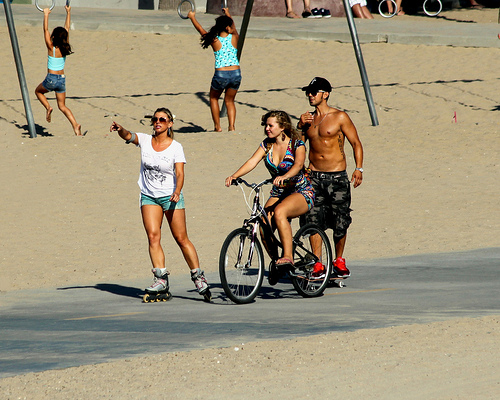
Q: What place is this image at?
A: It is at the walkway.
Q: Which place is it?
A: It is a walkway.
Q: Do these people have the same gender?
A: No, they are both male and female.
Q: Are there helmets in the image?
A: No, there are no helmets.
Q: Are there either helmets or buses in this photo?
A: No, there are no helmets or buses.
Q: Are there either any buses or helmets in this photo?
A: No, there are no helmets or buses.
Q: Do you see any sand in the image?
A: Yes, there is sand.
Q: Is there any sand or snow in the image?
A: Yes, there is sand.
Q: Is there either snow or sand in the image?
A: Yes, there is sand.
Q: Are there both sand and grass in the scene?
A: No, there is sand but no grass.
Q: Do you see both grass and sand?
A: No, there is sand but no grass.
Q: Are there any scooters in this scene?
A: No, there are no scooters.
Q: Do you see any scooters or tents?
A: No, there are no scooters or tents.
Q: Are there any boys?
A: No, there are no boys.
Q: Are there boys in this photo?
A: No, there are no boys.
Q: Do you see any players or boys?
A: No, there are no boys or players.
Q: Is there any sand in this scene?
A: Yes, there is sand.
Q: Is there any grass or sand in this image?
A: Yes, there is sand.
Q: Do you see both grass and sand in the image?
A: No, there is sand but no grass.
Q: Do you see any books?
A: No, there are no books.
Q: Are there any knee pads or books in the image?
A: No, there are no books or knee pads.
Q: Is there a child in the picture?
A: No, there are no children.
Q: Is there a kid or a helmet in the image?
A: No, there are no children or helmets.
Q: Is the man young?
A: Yes, the man is young.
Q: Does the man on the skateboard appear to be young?
A: Yes, the man is young.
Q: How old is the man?
A: The man is young.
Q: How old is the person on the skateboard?
A: The man is young.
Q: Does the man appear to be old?
A: No, the man is young.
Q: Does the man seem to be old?
A: No, the man is young.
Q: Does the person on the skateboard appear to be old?
A: No, the man is young.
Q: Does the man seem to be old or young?
A: The man is young.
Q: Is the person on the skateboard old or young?
A: The man is young.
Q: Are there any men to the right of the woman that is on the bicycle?
A: Yes, there is a man to the right of the woman.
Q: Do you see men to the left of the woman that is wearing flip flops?
A: No, the man is to the right of the woman.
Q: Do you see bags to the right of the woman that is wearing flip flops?
A: No, there is a man to the right of the woman.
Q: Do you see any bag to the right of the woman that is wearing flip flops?
A: No, there is a man to the right of the woman.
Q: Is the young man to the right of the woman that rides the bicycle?
A: Yes, the man is to the right of the woman.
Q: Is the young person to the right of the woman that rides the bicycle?
A: Yes, the man is to the right of the woman.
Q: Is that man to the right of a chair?
A: No, the man is to the right of the woman.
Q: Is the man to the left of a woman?
A: No, the man is to the right of a woman.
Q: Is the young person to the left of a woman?
A: No, the man is to the right of a woman.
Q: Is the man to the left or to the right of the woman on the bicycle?
A: The man is to the right of the woman.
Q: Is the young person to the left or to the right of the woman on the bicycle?
A: The man is to the right of the woman.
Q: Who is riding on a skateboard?
A: The man is riding on a skateboard.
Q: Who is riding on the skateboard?
A: The man is riding on a skateboard.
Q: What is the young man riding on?
A: The man is riding on a skateboard.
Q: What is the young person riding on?
A: The man is riding on a skateboard.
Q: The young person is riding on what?
A: The man is riding on a skateboard.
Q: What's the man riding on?
A: The man is riding on a skateboard.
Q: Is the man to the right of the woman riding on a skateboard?
A: Yes, the man is riding on a skateboard.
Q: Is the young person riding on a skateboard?
A: Yes, the man is riding on a skateboard.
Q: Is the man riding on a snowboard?
A: No, the man is riding on a skateboard.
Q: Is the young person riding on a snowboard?
A: No, the man is riding on a skateboard.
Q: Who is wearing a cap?
A: The man is wearing a cap.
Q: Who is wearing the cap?
A: The man is wearing a cap.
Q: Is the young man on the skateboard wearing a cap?
A: Yes, the man is wearing a cap.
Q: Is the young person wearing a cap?
A: Yes, the man is wearing a cap.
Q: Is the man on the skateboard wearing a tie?
A: No, the man is wearing a cap.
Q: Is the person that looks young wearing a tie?
A: No, the man is wearing a cap.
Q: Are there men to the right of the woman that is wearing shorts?
A: Yes, there is a man to the right of the woman.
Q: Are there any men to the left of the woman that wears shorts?
A: No, the man is to the right of the woman.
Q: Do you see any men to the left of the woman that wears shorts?
A: No, the man is to the right of the woman.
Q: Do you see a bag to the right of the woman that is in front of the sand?
A: No, there is a man to the right of the woman.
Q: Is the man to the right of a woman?
A: Yes, the man is to the right of a woman.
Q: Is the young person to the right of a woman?
A: Yes, the man is to the right of a woman.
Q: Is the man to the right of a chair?
A: No, the man is to the right of a woman.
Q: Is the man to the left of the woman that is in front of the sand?
A: No, the man is to the right of the woman.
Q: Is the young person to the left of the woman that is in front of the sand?
A: No, the man is to the right of the woman.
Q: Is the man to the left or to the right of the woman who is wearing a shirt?
A: The man is to the right of the woman.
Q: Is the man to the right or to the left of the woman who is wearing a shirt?
A: The man is to the right of the woman.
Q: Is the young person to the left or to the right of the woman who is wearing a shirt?
A: The man is to the right of the woman.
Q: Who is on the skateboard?
A: The man is on the skateboard.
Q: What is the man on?
A: The man is on the skateboard.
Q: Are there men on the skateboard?
A: Yes, there is a man on the skateboard.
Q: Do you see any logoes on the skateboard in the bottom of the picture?
A: No, there is a man on the skateboard.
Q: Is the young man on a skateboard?
A: Yes, the man is on a skateboard.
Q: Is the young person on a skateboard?
A: Yes, the man is on a skateboard.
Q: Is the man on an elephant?
A: No, the man is on a skateboard.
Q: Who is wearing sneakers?
A: The man is wearing sneakers.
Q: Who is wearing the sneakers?
A: The man is wearing sneakers.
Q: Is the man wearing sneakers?
A: Yes, the man is wearing sneakers.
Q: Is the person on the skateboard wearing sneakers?
A: Yes, the man is wearing sneakers.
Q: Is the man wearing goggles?
A: No, the man is wearing sneakers.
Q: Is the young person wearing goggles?
A: No, the man is wearing sneakers.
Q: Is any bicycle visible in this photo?
A: Yes, there is a bicycle.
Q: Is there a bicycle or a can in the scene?
A: Yes, there is a bicycle.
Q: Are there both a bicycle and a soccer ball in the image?
A: No, there is a bicycle but no soccer balls.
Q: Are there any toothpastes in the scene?
A: No, there are no toothpastes.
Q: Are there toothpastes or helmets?
A: No, there are no toothpastes or helmets.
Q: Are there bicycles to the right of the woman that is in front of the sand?
A: Yes, there is a bicycle to the right of the woman.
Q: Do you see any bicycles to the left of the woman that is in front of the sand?
A: No, the bicycle is to the right of the woman.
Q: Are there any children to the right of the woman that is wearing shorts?
A: No, there is a bicycle to the right of the woman.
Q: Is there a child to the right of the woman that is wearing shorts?
A: No, there is a bicycle to the right of the woman.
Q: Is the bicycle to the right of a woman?
A: Yes, the bicycle is to the right of a woman.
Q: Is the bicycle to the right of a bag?
A: No, the bicycle is to the right of a woman.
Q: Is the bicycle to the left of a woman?
A: No, the bicycle is to the right of a woman.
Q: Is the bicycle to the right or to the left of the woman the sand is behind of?
A: The bicycle is to the right of the woman.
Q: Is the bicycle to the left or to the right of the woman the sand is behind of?
A: The bicycle is to the right of the woman.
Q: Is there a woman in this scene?
A: Yes, there is a woman.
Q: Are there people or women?
A: Yes, there is a woman.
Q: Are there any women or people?
A: Yes, there is a woman.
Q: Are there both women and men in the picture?
A: Yes, there are both a woman and a man.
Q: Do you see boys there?
A: No, there are no boys.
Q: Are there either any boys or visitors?
A: No, there are no boys or visitors.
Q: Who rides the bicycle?
A: The woman rides the bicycle.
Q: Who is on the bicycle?
A: The woman is on the bicycle.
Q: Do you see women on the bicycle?
A: Yes, there is a woman on the bicycle.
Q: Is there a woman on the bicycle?
A: Yes, there is a woman on the bicycle.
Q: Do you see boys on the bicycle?
A: No, there is a woman on the bicycle.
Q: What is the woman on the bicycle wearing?
A: The woman is wearing flip flops.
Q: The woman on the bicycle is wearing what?
A: The woman is wearing flip flops.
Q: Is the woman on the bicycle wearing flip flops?
A: Yes, the woman is wearing flip flops.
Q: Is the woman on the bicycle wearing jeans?
A: No, the woman is wearing flip flops.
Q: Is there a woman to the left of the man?
A: Yes, there is a woman to the left of the man.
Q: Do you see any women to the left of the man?
A: Yes, there is a woman to the left of the man.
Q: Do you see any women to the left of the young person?
A: Yes, there is a woman to the left of the man.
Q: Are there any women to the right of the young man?
A: No, the woman is to the left of the man.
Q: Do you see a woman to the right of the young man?
A: No, the woman is to the left of the man.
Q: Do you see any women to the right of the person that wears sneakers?
A: No, the woman is to the left of the man.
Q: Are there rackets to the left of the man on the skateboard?
A: No, there is a woman to the left of the man.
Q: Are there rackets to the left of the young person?
A: No, there is a woman to the left of the man.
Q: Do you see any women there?
A: Yes, there is a woman.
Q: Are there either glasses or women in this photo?
A: Yes, there is a woman.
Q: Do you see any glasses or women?
A: Yes, there is a woman.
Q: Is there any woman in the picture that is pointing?
A: Yes, there is a woman that is pointing.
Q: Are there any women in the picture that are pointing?
A: Yes, there is a woman that is pointing.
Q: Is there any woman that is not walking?
A: Yes, there is a woman that is pointing.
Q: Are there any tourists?
A: No, there are no tourists.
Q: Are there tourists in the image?
A: No, there are no tourists.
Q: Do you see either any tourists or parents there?
A: No, there are no tourists or parents.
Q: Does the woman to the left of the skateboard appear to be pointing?
A: Yes, the woman is pointing.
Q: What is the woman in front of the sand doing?
A: The woman is pointing.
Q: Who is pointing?
A: The woman is pointing.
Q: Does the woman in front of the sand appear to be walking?
A: No, the woman is pointing.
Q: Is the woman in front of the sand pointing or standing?
A: The woman is pointing.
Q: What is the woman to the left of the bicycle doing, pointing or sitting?
A: The woman is pointing.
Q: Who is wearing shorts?
A: The woman is wearing shorts.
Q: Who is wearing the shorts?
A: The woman is wearing shorts.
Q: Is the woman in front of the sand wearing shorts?
A: Yes, the woman is wearing shorts.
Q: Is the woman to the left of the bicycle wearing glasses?
A: No, the woman is wearing shorts.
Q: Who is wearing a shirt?
A: The woman is wearing a shirt.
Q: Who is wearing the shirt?
A: The woman is wearing a shirt.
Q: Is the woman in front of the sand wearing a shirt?
A: Yes, the woman is wearing a shirt.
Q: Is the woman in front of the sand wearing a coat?
A: No, the woman is wearing a shirt.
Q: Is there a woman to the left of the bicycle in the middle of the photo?
A: Yes, there is a woman to the left of the bicycle.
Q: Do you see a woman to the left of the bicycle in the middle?
A: Yes, there is a woman to the left of the bicycle.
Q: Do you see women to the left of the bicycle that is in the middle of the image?
A: Yes, there is a woman to the left of the bicycle.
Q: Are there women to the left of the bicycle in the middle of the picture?
A: Yes, there is a woman to the left of the bicycle.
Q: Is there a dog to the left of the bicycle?
A: No, there is a woman to the left of the bicycle.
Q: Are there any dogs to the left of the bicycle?
A: No, there is a woman to the left of the bicycle.